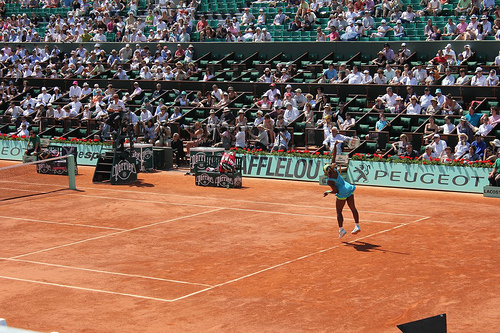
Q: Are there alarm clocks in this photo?
A: No, there are no alarm clocks.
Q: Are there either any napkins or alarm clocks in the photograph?
A: No, there are no alarm clocks or napkins.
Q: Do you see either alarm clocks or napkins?
A: No, there are no alarm clocks or napkins.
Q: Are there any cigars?
A: No, there are no cigars.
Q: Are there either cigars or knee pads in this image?
A: No, there are no cigars or knee pads.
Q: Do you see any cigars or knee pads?
A: No, there are no cigars or knee pads.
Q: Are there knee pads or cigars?
A: No, there are no cigars or knee pads.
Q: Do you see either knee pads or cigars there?
A: No, there are no cigars or knee pads.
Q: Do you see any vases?
A: No, there are no vases.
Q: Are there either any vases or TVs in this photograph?
A: No, there are no vases or tvs.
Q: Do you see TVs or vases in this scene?
A: No, there are no vases or tvs.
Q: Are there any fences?
A: No, there are no fences.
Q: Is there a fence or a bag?
A: No, there are no fences or bags.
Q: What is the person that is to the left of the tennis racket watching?
A: The person is watching the match.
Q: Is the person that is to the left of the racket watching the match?
A: Yes, the person is watching the match.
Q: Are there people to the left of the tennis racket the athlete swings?
A: Yes, there is a person to the left of the racket.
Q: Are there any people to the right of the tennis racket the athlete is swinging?
A: No, the person is to the left of the tennis racket.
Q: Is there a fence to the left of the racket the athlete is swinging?
A: No, there is a person to the left of the tennis racket.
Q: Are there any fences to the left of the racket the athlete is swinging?
A: No, there is a person to the left of the tennis racket.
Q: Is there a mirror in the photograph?
A: No, there are no mirrors.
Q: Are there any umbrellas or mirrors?
A: No, there are no mirrors or umbrellas.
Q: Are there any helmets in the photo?
A: No, there are no helmets.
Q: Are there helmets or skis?
A: No, there are no helmets or skis.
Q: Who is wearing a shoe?
A: The athlete is wearing a shoe.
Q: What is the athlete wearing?
A: The athlete is wearing a shoe.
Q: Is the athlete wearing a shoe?
A: Yes, the athlete is wearing a shoe.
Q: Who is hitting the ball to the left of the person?
A: The athlete is hitting the ball.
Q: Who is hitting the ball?
A: The athlete is hitting the ball.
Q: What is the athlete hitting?
A: The athlete is hitting the ball.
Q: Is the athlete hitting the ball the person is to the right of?
A: Yes, the athlete is hitting the ball.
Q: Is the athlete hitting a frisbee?
A: No, the athlete is hitting the ball.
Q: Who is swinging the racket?
A: The athlete is swinging the racket.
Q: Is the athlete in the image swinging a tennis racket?
A: Yes, the athlete is swinging a tennis racket.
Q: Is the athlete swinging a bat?
A: No, the athlete is swinging a tennis racket.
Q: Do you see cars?
A: No, there are no cars.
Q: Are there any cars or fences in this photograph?
A: No, there are no cars or fences.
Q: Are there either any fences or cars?
A: No, there are no cars or fences.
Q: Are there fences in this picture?
A: No, there are no fences.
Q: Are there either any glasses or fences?
A: No, there are no fences or glasses.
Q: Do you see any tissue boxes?
A: No, there are no tissue boxes.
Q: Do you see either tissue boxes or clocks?
A: No, there are no tissue boxes or clocks.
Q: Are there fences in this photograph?
A: No, there are no fences.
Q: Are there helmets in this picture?
A: No, there are no helmets.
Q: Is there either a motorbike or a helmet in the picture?
A: No, there are no helmets or motorcycles.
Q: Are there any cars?
A: No, there are no cars.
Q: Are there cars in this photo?
A: No, there are no cars.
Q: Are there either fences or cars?
A: No, there are no cars or fences.